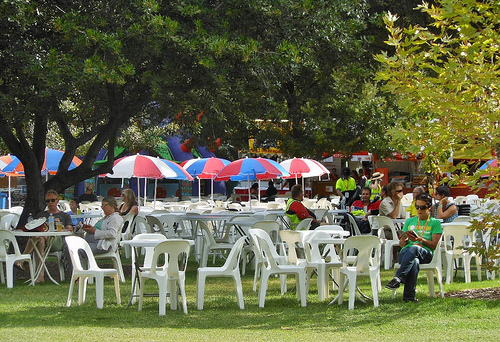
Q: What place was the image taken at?
A: It was taken at the lawn.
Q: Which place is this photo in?
A: It is at the lawn.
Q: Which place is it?
A: It is a lawn.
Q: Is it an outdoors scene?
A: Yes, it is outdoors.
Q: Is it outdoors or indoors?
A: It is outdoors.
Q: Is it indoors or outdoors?
A: It is outdoors.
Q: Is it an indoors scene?
A: No, it is outdoors.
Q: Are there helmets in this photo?
A: No, there are no helmets.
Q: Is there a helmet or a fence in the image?
A: No, there are no helmets or fences.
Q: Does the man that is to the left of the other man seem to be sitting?
A: Yes, the man is sitting.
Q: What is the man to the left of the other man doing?
A: The man is sitting.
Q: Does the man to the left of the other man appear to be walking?
A: No, the man is sitting.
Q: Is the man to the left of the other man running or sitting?
A: The man is sitting.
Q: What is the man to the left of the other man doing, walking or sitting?
A: The man is sitting.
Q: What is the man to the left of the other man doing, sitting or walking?
A: The man is sitting.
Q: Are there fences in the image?
A: No, there are no fences.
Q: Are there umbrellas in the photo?
A: Yes, there are umbrellas.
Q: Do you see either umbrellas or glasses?
A: Yes, there are umbrellas.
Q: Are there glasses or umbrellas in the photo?
A: Yes, there are umbrellas.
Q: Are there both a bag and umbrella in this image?
A: No, there are umbrellas but no bags.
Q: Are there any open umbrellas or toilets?
A: Yes, there are open umbrellas.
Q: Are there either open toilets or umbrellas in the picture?
A: Yes, there are open umbrellas.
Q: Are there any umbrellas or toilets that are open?
A: Yes, the umbrellas are open.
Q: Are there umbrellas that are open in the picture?
A: Yes, there are open umbrellas.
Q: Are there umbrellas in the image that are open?
A: Yes, there are umbrellas that are open.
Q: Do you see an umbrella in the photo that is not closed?
A: Yes, there are open umbrellas.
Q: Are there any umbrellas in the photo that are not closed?
A: Yes, there are open umbrellas.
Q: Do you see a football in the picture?
A: No, there are no footballs.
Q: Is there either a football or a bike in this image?
A: No, there are no footballs or bikes.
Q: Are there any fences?
A: No, there are no fences.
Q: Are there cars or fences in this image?
A: No, there are no fences or cars.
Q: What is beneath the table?
A: The lawn is beneath the table.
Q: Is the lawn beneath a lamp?
A: No, the lawn is beneath the table.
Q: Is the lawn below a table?
A: Yes, the lawn is below a table.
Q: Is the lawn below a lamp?
A: No, the lawn is below a table.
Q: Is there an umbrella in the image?
A: Yes, there are umbrellas.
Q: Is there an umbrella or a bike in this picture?
A: Yes, there are umbrellas.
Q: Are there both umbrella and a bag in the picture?
A: No, there are umbrellas but no bags.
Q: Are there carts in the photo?
A: No, there are no carts.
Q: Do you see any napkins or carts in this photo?
A: No, there are no carts or napkins.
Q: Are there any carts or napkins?
A: No, there are no carts or napkins.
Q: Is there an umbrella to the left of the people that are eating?
A: Yes, there are umbrellas to the left of the people.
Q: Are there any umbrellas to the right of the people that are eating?
A: No, the umbrellas are to the left of the people.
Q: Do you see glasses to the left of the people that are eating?
A: No, there are umbrellas to the left of the people.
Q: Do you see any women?
A: Yes, there is a woman.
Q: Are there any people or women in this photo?
A: Yes, there is a woman.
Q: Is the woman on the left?
A: Yes, the woman is on the left of the image.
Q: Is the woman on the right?
A: No, the woman is on the left of the image.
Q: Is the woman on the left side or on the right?
A: The woman is on the left of the image.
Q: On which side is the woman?
A: The woman is on the left of the image.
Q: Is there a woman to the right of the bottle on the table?
A: Yes, there is a woman to the right of the bottle.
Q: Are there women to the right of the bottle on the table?
A: Yes, there is a woman to the right of the bottle.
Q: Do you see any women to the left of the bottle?
A: No, the woman is to the right of the bottle.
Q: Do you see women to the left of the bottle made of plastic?
A: No, the woman is to the right of the bottle.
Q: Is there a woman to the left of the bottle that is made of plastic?
A: No, the woman is to the right of the bottle.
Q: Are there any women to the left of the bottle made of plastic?
A: No, the woman is to the right of the bottle.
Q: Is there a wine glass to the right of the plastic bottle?
A: No, there is a woman to the right of the bottle.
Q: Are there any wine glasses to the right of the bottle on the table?
A: No, there is a woman to the right of the bottle.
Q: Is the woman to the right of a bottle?
A: Yes, the woman is to the right of a bottle.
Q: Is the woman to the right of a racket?
A: No, the woman is to the right of a bottle.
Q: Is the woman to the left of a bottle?
A: No, the woman is to the right of a bottle.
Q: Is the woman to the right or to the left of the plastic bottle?
A: The woman is to the right of the bottle.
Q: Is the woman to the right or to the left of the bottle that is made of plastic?
A: The woman is to the right of the bottle.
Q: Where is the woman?
A: The woman is at the table.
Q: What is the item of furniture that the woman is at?
A: The piece of furniture is a table.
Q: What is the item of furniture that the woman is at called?
A: The piece of furniture is a table.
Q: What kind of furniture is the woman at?
A: The woman is at the table.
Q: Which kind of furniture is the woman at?
A: The woman is at the table.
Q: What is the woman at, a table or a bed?
A: The woman is at a table.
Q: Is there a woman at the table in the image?
A: Yes, there is a woman at the table.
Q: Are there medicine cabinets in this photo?
A: No, there are no medicine cabinets.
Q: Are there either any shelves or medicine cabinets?
A: No, there are no medicine cabinets or shelves.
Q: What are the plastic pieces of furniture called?
A: The pieces of furniture are chairs.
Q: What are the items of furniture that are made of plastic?
A: The pieces of furniture are chairs.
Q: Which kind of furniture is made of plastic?
A: The furniture is chairs.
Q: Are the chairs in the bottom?
A: Yes, the chairs are in the bottom of the image.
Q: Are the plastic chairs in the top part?
A: No, the chairs are in the bottom of the image.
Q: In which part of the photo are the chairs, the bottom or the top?
A: The chairs are in the bottom of the image.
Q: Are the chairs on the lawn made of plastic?
A: Yes, the chairs are made of plastic.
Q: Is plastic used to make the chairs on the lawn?
A: Yes, the chairs are made of plastic.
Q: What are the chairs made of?
A: The chairs are made of plastic.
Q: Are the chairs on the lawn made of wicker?
A: No, the chairs are made of plastic.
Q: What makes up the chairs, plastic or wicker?
A: The chairs are made of plastic.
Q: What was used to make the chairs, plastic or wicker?
A: The chairs are made of plastic.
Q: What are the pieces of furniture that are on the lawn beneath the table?
A: The pieces of furniture are chairs.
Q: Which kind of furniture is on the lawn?
A: The pieces of furniture are chairs.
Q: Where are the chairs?
A: The chairs are on the lawn.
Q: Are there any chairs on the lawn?
A: Yes, there are chairs on the lawn.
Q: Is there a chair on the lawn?
A: Yes, there are chairs on the lawn.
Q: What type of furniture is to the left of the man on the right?
A: The pieces of furniture are chairs.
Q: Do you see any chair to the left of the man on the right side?
A: Yes, there are chairs to the left of the man.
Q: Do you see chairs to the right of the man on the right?
A: No, the chairs are to the left of the man.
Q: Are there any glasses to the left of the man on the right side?
A: No, there are chairs to the left of the man.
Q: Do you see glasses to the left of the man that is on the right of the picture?
A: No, there are chairs to the left of the man.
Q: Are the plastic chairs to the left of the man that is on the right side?
A: Yes, the chairs are to the left of the man.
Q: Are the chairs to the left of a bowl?
A: No, the chairs are to the left of the man.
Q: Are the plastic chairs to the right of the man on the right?
A: No, the chairs are to the left of the man.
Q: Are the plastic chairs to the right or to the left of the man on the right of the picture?
A: The chairs are to the left of the man.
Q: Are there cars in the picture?
A: No, there are no cars.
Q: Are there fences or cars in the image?
A: No, there are no cars or fences.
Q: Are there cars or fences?
A: No, there are no cars or fences.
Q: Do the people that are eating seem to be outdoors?
A: Yes, the people are outdoors.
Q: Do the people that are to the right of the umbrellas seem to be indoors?
A: No, the people are outdoors.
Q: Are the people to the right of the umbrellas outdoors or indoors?
A: The people are outdoors.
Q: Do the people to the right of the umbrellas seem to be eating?
A: Yes, the people are eating.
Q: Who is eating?
A: The people are eating.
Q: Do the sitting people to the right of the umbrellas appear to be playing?
A: No, the people are eating.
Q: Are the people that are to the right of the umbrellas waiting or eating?
A: The people are eating.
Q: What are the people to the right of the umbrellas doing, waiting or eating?
A: The people are eating.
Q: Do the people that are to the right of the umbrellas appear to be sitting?
A: Yes, the people are sitting.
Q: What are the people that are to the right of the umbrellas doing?
A: The people are sitting.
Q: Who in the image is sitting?
A: The people are sitting.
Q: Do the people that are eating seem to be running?
A: No, the people are sitting.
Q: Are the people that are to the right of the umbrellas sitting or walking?
A: The people are sitting.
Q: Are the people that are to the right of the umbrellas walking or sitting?
A: The people are sitting.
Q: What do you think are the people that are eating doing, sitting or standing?
A: The people are sitting.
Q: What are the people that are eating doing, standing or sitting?
A: The people are sitting.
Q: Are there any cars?
A: No, there are no cars.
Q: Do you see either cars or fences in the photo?
A: No, there are no cars or fences.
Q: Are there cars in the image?
A: No, there are no cars.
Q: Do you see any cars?
A: No, there are no cars.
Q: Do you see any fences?
A: No, there are no fences.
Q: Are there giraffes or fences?
A: No, there are no fences or giraffes.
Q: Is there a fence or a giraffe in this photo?
A: No, there are no fences or giraffes.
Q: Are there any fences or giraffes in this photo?
A: No, there are no fences or giraffes.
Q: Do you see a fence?
A: No, there are no fences.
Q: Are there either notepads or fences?
A: No, there are no fences or notepads.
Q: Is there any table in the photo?
A: Yes, there is a table.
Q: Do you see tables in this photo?
A: Yes, there is a table.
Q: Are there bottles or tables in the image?
A: Yes, there is a table.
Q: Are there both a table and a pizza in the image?
A: No, there is a table but no pizzas.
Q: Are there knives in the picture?
A: No, there are no knives.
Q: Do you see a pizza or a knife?
A: No, there are no knives or pizzas.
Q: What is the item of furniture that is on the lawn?
A: The piece of furniture is a table.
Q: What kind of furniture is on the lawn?
A: The piece of furniture is a table.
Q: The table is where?
A: The table is on the lawn.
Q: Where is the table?
A: The table is on the lawn.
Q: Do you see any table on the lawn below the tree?
A: Yes, there is a table on the lawn.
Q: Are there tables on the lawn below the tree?
A: Yes, there is a table on the lawn.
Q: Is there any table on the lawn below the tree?
A: Yes, there is a table on the lawn.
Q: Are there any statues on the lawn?
A: No, there is a table on the lawn.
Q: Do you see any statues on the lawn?
A: No, there is a table on the lawn.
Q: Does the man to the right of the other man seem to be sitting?
A: Yes, the man is sitting.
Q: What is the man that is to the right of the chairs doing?
A: The man is sitting.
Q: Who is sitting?
A: The man is sitting.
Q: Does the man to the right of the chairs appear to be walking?
A: No, the man is sitting.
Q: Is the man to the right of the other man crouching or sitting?
A: The man is sitting.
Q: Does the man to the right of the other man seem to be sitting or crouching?
A: The man is sitting.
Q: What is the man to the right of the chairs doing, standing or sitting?
A: The man is sitting.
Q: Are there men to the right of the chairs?
A: Yes, there is a man to the right of the chairs.